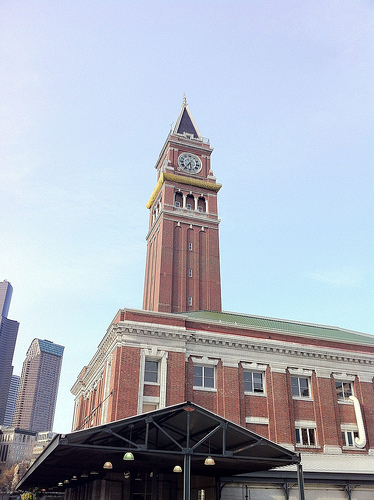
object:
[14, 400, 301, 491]
awning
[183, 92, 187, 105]
weather vane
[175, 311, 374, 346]
green roof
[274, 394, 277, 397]
brick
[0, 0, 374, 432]
sky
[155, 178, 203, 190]
divider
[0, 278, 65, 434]
sky scrapers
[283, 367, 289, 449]
windows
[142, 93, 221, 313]
tower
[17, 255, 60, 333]
artichoke pizza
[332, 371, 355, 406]
window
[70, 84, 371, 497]
brick building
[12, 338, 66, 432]
office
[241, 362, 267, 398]
window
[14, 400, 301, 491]
covered area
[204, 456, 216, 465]
lamp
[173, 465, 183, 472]
lamp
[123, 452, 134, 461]
lamp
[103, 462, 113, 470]
lamp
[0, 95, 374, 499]
city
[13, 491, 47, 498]
trees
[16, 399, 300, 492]
ceiling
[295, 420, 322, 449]
window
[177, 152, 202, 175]
clock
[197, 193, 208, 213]
windows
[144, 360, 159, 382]
window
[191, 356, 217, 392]
window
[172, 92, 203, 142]
steeple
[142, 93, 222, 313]
clock tower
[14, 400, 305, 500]
pavilion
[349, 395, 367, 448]
tube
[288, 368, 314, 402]
window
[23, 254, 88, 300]
cloud